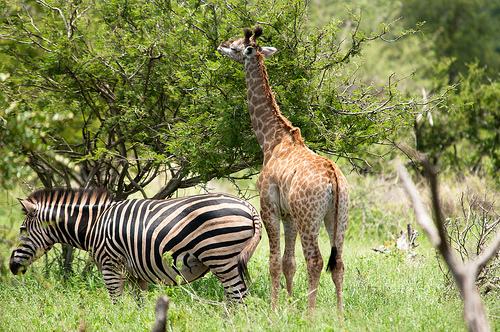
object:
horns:
[243, 25, 265, 45]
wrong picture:
[3, 74, 76, 177]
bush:
[387, 86, 499, 331]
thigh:
[298, 207, 325, 246]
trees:
[381, 57, 499, 332]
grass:
[350, 279, 452, 331]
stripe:
[164, 204, 253, 253]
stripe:
[179, 205, 257, 237]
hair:
[26, 187, 128, 198]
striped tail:
[236, 204, 263, 281]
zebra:
[7, 183, 265, 312]